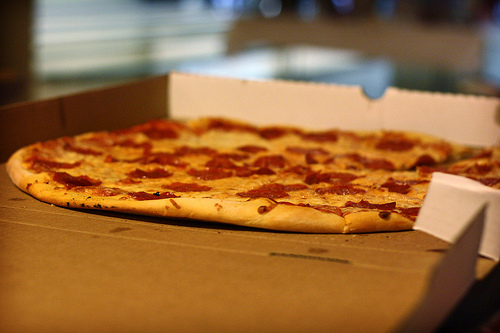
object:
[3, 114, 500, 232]
pizza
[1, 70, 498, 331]
box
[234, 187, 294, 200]
pepperoni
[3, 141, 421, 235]
crust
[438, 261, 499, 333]
counter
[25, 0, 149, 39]
window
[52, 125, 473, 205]
cheese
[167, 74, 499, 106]
perforated top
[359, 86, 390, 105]
hole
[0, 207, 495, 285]
section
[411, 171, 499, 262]
cardboard flap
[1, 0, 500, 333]
room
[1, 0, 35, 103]
wall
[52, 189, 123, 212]
seasoning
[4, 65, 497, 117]
perforated edge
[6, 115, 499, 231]
slices